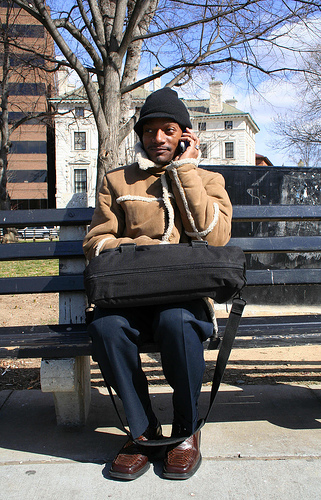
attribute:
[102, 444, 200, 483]
shoes — brown, dark, leather, square toed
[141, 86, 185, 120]
hat — black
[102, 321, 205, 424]
pants — blue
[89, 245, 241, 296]
bag — black, large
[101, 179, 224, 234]
jacket — black, white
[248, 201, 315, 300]
bench — concrete, black, dark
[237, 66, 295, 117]
clouds — white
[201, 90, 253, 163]
building — white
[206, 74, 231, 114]
chimney — white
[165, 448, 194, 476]
dress shoe — brown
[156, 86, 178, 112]
cap — black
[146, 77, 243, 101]
house — white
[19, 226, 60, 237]
car — parked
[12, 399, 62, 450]
shadow — dark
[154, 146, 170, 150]
mustache — black, dark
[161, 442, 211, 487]
shoe — brown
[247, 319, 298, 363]
sidewalk — paved, white